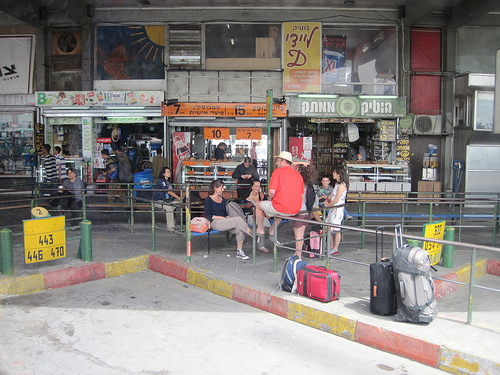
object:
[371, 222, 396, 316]
luggage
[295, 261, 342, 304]
luggage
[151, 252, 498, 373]
curb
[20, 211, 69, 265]
sign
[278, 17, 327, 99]
sign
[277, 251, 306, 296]
back pack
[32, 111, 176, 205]
stores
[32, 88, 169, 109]
sign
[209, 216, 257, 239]
leg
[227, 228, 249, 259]
leg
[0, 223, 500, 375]
ground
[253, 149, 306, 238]
guy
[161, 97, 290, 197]
food stand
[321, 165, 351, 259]
person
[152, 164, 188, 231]
person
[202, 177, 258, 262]
person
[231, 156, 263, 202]
person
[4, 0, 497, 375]
bus terminal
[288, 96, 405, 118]
sign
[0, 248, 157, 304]
curb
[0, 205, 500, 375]
sidewalk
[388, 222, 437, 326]
bags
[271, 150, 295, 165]
white hat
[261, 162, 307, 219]
shirt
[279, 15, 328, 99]
sign.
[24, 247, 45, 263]
numbers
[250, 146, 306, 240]
man